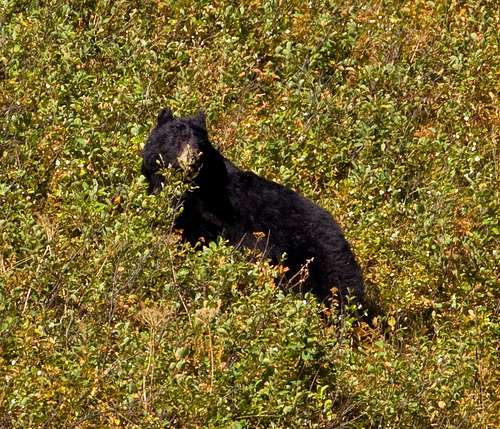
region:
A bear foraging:
[155, 128, 204, 183]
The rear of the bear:
[340, 253, 351, 285]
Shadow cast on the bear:
[204, 178, 219, 196]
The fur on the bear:
[312, 223, 331, 248]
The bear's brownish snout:
[182, 151, 187, 162]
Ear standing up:
[161, 111, 168, 118]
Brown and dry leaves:
[362, 41, 374, 52]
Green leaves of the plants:
[108, 149, 125, 171]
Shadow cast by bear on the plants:
[371, 306, 386, 319]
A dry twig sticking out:
[145, 309, 161, 324]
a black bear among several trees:
[140, 103, 394, 325]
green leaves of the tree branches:
[343, 111, 473, 225]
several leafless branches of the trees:
[101, 267, 216, 398]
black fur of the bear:
[245, 195, 321, 258]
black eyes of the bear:
[158, 134, 211, 154]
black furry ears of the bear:
[152, 103, 211, 127]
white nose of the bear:
[178, 145, 202, 172]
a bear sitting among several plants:
[128, 93, 379, 322]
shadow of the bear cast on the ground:
[369, 280, 444, 346]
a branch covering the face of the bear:
[155, 125, 212, 227]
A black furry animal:
[141, 106, 383, 346]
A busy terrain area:
[5, 7, 490, 414]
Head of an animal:
[141, 106, 208, 199]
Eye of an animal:
[178, 131, 190, 143]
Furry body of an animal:
[170, 158, 362, 300]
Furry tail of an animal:
[359, 296, 392, 335]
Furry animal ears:
[154, 106, 210, 125]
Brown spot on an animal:
[174, 144, 198, 168]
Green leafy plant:
[18, 235, 65, 336]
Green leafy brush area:
[3, 8, 485, 422]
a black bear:
[137, 108, 376, 322]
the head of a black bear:
[134, 101, 214, 181]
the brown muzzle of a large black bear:
[172, 140, 213, 185]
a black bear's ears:
[155, 108, 209, 127]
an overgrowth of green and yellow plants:
[6, 301, 223, 427]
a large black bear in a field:
[132, 98, 441, 366]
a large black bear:
[125, 98, 380, 318]